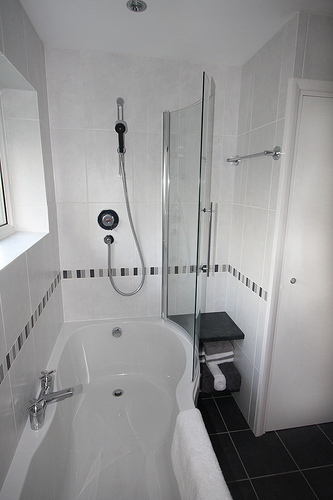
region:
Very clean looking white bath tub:
[56, 318, 183, 497]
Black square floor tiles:
[229, 433, 329, 493]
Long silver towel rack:
[225, 144, 281, 163]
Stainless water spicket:
[28, 366, 72, 427]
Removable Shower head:
[114, 121, 134, 207]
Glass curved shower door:
[160, 103, 207, 338]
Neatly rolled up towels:
[199, 360, 241, 392]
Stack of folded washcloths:
[202, 342, 234, 362]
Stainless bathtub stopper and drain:
[111, 385, 122, 396]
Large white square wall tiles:
[219, 167, 274, 262]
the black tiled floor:
[226, 431, 329, 494]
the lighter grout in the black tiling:
[273, 430, 311, 481]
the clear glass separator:
[157, 71, 201, 378]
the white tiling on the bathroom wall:
[53, 63, 104, 188]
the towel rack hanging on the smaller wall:
[224, 151, 279, 161]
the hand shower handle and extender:
[106, 93, 145, 297]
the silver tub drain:
[112, 386, 124, 395]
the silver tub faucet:
[27, 362, 74, 432]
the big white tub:
[37, 311, 194, 498]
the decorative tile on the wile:
[62, 264, 227, 276]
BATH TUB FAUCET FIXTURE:
[23, 364, 76, 433]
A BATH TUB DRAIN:
[105, 386, 134, 403]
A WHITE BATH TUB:
[1, 314, 228, 497]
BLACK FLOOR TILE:
[233, 431, 307, 499]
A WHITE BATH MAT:
[162, 405, 236, 499]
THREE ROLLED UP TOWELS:
[192, 361, 244, 396]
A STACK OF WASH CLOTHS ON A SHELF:
[192, 337, 238, 365]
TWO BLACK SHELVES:
[166, 305, 252, 398]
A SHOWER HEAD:
[107, 107, 132, 150]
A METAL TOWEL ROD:
[213, 142, 291, 167]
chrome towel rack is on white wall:
[224, 145, 284, 166]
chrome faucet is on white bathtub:
[28, 367, 73, 429]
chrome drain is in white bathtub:
[109, 383, 125, 396]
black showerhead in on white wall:
[106, 118, 137, 170]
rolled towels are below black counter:
[196, 341, 242, 395]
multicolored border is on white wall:
[60, 261, 228, 284]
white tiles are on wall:
[236, 168, 264, 261]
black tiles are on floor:
[231, 440, 328, 483]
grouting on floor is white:
[244, 461, 311, 482]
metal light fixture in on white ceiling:
[116, 0, 158, 18]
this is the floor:
[249, 442, 323, 491]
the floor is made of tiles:
[245, 451, 299, 481]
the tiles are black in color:
[248, 451, 318, 494]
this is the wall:
[56, 68, 98, 182]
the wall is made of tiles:
[53, 123, 99, 191]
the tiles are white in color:
[58, 74, 107, 196]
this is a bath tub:
[21, 319, 214, 498]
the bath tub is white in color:
[76, 337, 107, 376]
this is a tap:
[31, 387, 50, 417]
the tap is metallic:
[31, 411, 41, 422]